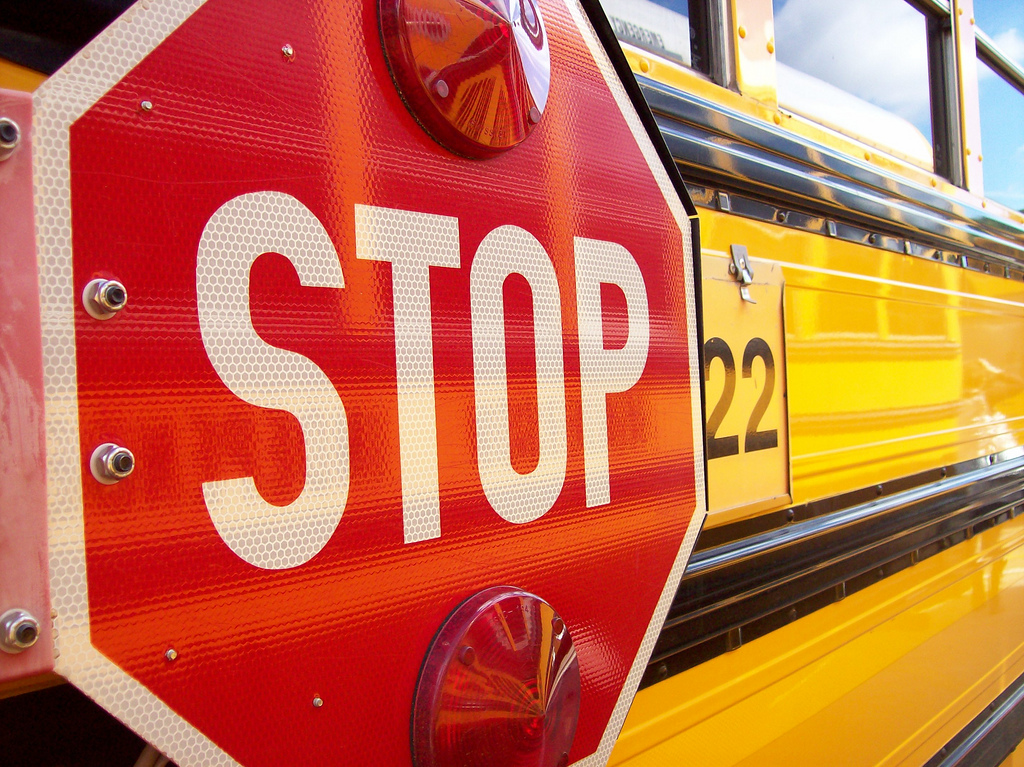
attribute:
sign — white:
[67, 61, 709, 748]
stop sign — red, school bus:
[41, 0, 713, 757]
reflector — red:
[401, 577, 583, 761]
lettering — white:
[190, 184, 655, 573]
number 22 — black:
[697, 326, 786, 460]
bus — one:
[1, 6, 1019, 761]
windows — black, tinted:
[762, 1, 994, 172]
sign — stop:
[94, 111, 581, 716]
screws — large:
[38, 245, 159, 358]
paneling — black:
[665, 68, 1018, 244]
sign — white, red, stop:
[47, 50, 743, 716]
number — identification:
[648, 286, 860, 570]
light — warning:
[399, 538, 616, 727]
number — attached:
[682, 329, 795, 476]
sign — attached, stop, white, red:
[159, 67, 689, 698]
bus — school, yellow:
[203, 44, 1012, 731]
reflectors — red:
[352, 0, 638, 754]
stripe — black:
[699, 95, 1008, 240]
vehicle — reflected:
[609, 95, 1001, 521]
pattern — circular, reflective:
[216, 197, 331, 286]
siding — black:
[639, 102, 1022, 258]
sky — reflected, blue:
[861, 28, 1022, 195]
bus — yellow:
[739, 20, 949, 742]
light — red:
[409, 575, 615, 748]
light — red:
[392, 14, 565, 153]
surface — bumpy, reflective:
[138, 111, 393, 649]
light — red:
[410, 1, 588, 200]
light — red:
[382, 580, 618, 758]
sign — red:
[177, 156, 813, 764]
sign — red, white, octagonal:
[82, 35, 789, 764]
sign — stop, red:
[58, 7, 763, 759]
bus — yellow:
[624, 46, 996, 764]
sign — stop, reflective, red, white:
[47, 18, 666, 755]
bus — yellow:
[596, 35, 1020, 725]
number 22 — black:
[700, 334, 776, 462]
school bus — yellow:
[24, 23, 994, 737]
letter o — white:
[469, 228, 563, 525]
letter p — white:
[575, 222, 655, 506]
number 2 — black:
[742, 339, 775, 450]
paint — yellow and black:
[767, 455, 973, 685]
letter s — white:
[195, 183, 356, 570]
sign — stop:
[24, 1, 709, 758]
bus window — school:
[767, 1, 936, 164]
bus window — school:
[970, 8, 994, 212]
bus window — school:
[605, 4, 709, 72]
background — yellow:
[687, 244, 791, 526]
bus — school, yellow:
[42, 29, 985, 734]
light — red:
[391, 576, 605, 764]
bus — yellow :
[665, 32, 1020, 763]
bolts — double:
[73, 267, 141, 492]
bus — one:
[704, 1, 1009, 743]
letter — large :
[192, 179, 367, 577]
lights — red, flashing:
[348, 3, 578, 747]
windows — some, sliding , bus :
[620, 12, 1009, 209]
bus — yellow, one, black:
[641, 12, 1009, 749]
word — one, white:
[188, 170, 651, 562]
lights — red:
[388, 73, 579, 763]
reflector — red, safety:
[389, 582, 586, 764]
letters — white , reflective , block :
[180, 179, 649, 571]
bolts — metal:
[75, 272, 145, 508]